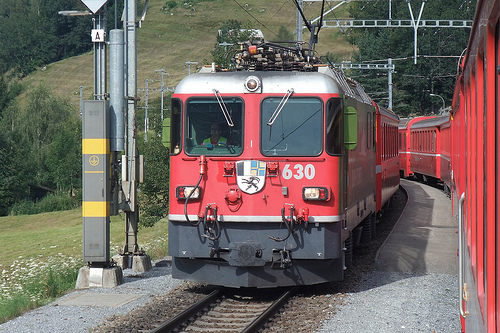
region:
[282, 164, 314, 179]
the 630 in front of the train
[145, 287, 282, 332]
the train tracks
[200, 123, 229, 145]
the driver in front of the train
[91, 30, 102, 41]
the little white sign with A on it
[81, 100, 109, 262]
the gray and yellow box next to the track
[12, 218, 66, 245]
the green grass next to the tracks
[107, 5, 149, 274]
the metal poles next to the track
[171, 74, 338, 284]
the front of the train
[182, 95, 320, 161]
the two windows in front of the train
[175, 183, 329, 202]
the train lights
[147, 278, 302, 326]
tracks in front of a train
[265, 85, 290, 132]
a windshield wiper on a train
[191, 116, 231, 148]
a man in a train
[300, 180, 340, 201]
a headlight on a train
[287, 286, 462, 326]
gravel along the tracks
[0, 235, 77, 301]
white flowers at the edge of a field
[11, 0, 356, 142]
a mown green hill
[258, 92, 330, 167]
a window in the front of a train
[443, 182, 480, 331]
a hand rail on the side of a train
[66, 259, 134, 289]
the concrete base of a support beam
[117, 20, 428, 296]
the train is red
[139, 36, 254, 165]
an egineer drives the train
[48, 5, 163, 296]
rail equipment helps the train to ride the tracks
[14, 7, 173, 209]
green scenery in the backgorund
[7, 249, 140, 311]
white flowers along the side of the track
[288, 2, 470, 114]
electrical equipment to help the train move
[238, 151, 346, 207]
the number 630 is on this train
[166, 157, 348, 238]
two headlights are at the front of the train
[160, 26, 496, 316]
two trains are traveling opposite of each other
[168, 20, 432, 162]
some type of cable is on top of the train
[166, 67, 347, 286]
a train on the track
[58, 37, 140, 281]
a power generator on the side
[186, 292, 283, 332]
the rail way track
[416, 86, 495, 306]
side iron rods on the station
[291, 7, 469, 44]
iron rod placed on the top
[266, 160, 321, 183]
number of the train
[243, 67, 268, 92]
red light indicator of train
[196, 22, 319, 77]
laguage on top of the train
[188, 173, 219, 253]
pipe in front of train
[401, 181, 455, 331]
road on side of the train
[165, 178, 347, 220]
headlights on a red train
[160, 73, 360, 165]
red train windshield with windshield wipers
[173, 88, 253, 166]
window on a train with person inside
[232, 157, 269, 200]
white crest with blue, yellow and black design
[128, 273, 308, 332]
one set of train tracks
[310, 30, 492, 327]
two red trains beside each other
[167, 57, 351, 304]
front of red train engine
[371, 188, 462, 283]
gray concrete walkway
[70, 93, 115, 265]
metal box with yellow stripes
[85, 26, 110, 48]
sign with only the letter A